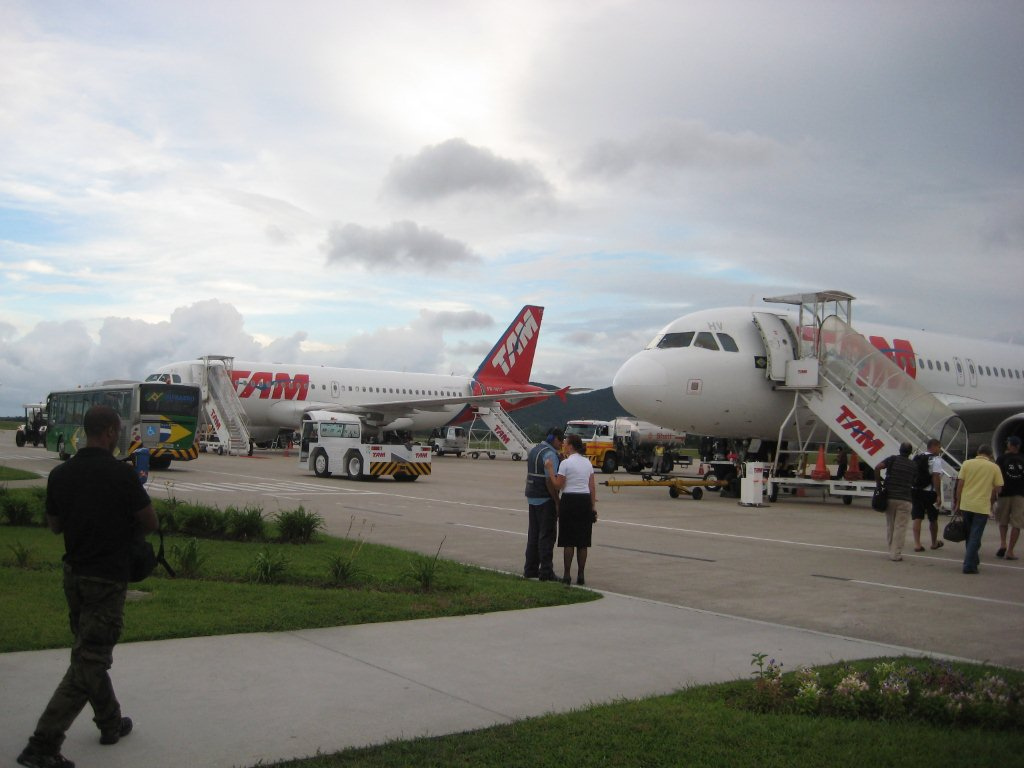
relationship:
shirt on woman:
[531, 420, 637, 496] [544, 420, 616, 546]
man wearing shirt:
[942, 433, 1009, 574] [946, 451, 1014, 516]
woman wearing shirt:
[548, 427, 598, 585] [557, 449, 605, 486]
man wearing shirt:
[873, 427, 921, 566] [877, 449, 925, 506]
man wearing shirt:
[11, 390, 169, 766] [38, 448, 162, 600]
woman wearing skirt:
[548, 427, 598, 585] [557, 487, 599, 552]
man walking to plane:
[16, 406, 159, 766] [602, 248, 1022, 490]